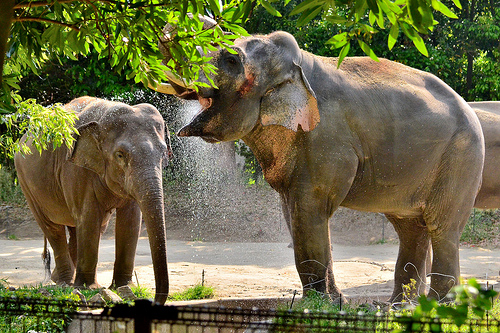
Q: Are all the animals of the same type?
A: Yes, all the animals are elephants.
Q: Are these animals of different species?
A: No, all the animals are elephants.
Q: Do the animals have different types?
A: No, all the animals are elephants.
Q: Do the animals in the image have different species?
A: No, all the animals are elephants.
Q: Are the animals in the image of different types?
A: No, all the animals are elephants.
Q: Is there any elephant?
A: Yes, there is an elephant.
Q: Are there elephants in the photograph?
A: Yes, there is an elephant.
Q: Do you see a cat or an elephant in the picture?
A: Yes, there is an elephant.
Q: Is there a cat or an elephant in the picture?
A: Yes, there is an elephant.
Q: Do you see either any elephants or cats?
A: Yes, there is an elephant.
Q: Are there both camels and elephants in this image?
A: No, there is an elephant but no camels.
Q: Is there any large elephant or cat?
A: Yes, there is a large elephant.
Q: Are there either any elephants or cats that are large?
A: Yes, the elephant is large.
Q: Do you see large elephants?
A: Yes, there is a large elephant.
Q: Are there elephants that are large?
A: Yes, there is an elephant that is large.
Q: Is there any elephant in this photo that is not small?
A: Yes, there is a large elephant.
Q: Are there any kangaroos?
A: No, there are no kangaroos.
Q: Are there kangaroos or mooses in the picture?
A: No, there are no kangaroos or mooses.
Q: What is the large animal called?
A: The animal is an elephant.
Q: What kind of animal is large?
A: The animal is an elephant.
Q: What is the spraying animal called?
A: The animal is an elephant.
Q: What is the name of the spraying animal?
A: The animal is an elephant.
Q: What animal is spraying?
A: The animal is an elephant.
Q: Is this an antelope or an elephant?
A: This is an elephant.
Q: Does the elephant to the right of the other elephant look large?
A: Yes, the elephant is large.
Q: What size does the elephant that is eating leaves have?
A: The elephant has large size.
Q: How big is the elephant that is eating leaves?
A: The elephant is large.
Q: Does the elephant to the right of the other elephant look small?
A: No, the elephant is large.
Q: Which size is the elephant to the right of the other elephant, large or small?
A: The elephant is large.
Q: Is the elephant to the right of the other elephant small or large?
A: The elephant is large.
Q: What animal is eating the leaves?
A: The elephant is eating the leaves.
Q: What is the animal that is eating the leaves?
A: The animal is an elephant.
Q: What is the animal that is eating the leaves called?
A: The animal is an elephant.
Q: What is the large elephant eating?
A: The elephant is eating leaves.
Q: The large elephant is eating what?
A: The elephant is eating leaves.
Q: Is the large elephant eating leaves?
A: Yes, the elephant is eating leaves.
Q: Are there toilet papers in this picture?
A: No, there are no toilet papers.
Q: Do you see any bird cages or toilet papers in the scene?
A: No, there are no toilet papers or bird cages.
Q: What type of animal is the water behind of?
A: The water is behind the elephant.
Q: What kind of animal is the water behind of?
A: The water is behind the elephant.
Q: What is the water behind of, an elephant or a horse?
A: The water is behind an elephant.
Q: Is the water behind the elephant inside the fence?
A: Yes, the water is behind the elephant.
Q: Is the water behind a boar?
A: No, the water is behind the elephant.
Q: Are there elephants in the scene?
A: Yes, there is an elephant.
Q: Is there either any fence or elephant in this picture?
A: Yes, there is an elephant.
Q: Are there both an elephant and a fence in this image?
A: Yes, there are both an elephant and a fence.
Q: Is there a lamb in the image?
A: No, there are no lambs.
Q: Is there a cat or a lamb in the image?
A: No, there are no lambs or cats.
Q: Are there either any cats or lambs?
A: No, there are no lambs or cats.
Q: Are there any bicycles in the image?
A: No, there are no bicycles.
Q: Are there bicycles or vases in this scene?
A: No, there are no bicycles or vases.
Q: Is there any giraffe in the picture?
A: No, there are no giraffes.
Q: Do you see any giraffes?
A: No, there are no giraffes.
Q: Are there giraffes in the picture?
A: No, there are no giraffes.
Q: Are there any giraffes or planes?
A: No, there are no giraffes or planes.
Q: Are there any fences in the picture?
A: Yes, there is a fence.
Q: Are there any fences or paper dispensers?
A: Yes, there is a fence.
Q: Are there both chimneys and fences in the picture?
A: No, there is a fence but no chimneys.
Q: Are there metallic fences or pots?
A: Yes, there is a metal fence.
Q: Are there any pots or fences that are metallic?
A: Yes, the fence is metallic.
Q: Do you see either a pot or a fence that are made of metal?
A: Yes, the fence is made of metal.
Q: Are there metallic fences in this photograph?
A: Yes, there is a metal fence.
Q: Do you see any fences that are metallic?
A: Yes, there is a fence that is metallic.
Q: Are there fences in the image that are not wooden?
A: Yes, there is a metallic fence.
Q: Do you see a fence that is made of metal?
A: Yes, there is a fence that is made of metal.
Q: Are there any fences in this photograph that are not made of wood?
A: Yes, there is a fence that is made of metal.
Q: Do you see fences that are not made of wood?
A: Yes, there is a fence that is made of metal.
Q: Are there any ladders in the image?
A: No, there are no ladders.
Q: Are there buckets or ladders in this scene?
A: No, there are no ladders or buckets.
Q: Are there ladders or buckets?
A: No, there are no ladders or buckets.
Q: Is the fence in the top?
A: No, the fence is in the bottom of the image.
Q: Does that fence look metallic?
A: Yes, the fence is metallic.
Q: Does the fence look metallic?
A: Yes, the fence is metallic.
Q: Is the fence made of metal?
A: Yes, the fence is made of metal.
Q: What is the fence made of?
A: The fence is made of metal.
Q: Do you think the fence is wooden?
A: No, the fence is metallic.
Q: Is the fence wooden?
A: No, the fence is metallic.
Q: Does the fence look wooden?
A: No, the fence is metallic.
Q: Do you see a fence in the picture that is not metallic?
A: No, there is a fence but it is metallic.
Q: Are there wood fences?
A: No, there is a fence but it is made of metal.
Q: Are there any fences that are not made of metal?
A: No, there is a fence but it is made of metal.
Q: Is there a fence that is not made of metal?
A: No, there is a fence but it is made of metal.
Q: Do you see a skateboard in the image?
A: No, there are no skateboards.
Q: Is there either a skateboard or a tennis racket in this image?
A: No, there are no skateboards or rackets.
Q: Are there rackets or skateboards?
A: No, there are no skateboards or rackets.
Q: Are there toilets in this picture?
A: No, there are no toilets.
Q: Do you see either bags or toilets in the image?
A: No, there are no toilets or bags.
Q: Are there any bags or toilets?
A: No, there are no toilets or bags.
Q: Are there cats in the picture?
A: No, there are no cats.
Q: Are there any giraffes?
A: No, there are no giraffes.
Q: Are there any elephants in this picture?
A: Yes, there is an elephant.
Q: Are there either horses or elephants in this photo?
A: Yes, there is an elephant.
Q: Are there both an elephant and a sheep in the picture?
A: No, there is an elephant but no sheep.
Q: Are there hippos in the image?
A: No, there are no hippos.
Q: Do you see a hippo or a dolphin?
A: No, there are no hippos or dolphins.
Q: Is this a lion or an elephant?
A: This is an elephant.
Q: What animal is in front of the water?
A: The elephant is in front of the water.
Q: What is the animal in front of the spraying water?
A: The animal is an elephant.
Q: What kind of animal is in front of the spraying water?
A: The animal is an elephant.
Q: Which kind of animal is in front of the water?
A: The animal is an elephant.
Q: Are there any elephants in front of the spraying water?
A: Yes, there is an elephant in front of the water.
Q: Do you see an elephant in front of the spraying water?
A: Yes, there is an elephant in front of the water.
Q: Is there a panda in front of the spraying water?
A: No, there is an elephant in front of the water.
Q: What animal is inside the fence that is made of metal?
A: The elephant is inside the fence.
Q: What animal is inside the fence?
A: The animal is an elephant.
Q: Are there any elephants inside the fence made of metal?
A: Yes, there is an elephant inside the fence.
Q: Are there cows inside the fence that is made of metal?
A: No, there is an elephant inside the fence.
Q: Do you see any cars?
A: No, there are no cars.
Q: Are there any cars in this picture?
A: No, there are no cars.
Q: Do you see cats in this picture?
A: No, there are no cats.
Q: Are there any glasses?
A: No, there are no glasses.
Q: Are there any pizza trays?
A: No, there are no pizza trays.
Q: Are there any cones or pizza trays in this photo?
A: No, there are no pizza trays or cones.